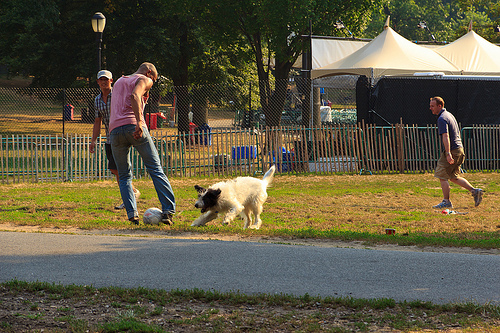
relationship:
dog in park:
[188, 164, 277, 230] [8, 22, 466, 329]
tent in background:
[310, 25, 487, 172] [10, 11, 499, 137]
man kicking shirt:
[106, 61, 177, 226] [106, 69, 152, 123]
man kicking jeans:
[106, 61, 177, 226] [103, 123, 181, 214]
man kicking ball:
[106, 61, 177, 226] [141, 200, 165, 227]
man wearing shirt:
[428, 96, 485, 212] [437, 107, 466, 153]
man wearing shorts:
[428, 96, 485, 212] [424, 145, 471, 177]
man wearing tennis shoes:
[428, 96, 485, 212] [428, 186, 483, 212]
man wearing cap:
[106, 61, 177, 226] [94, 63, 112, 78]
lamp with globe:
[92, 10, 106, 72] [93, 17, 105, 31]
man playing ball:
[108, 62, 175, 223] [144, 208, 162, 225]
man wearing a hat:
[86, 67, 118, 212] [94, 66, 115, 79]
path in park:
[6, 227, 496, 310] [17, 92, 477, 311]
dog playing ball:
[188, 164, 277, 230] [142, 207, 163, 226]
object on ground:
[264, 143, 291, 170] [2, 78, 497, 247]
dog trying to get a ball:
[189, 161, 278, 233] [143, 206, 163, 223]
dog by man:
[189, 161, 278, 233] [106, 58, 179, 226]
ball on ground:
[135, 202, 172, 227] [7, 178, 499, 248]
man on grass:
[413, 90, 485, 222] [296, 170, 481, 238]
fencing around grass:
[4, 120, 499, 182] [0, 168, 500, 251]